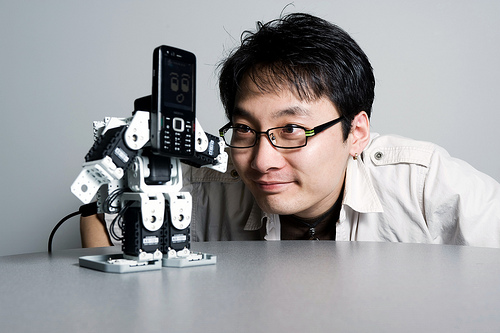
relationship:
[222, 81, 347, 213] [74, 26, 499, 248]
face of a man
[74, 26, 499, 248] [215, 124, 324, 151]
man wears glasses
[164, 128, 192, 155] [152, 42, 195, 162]
key pad on mobile phone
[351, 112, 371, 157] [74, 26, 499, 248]
ear of a man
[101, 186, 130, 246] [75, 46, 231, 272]
wires connected to robot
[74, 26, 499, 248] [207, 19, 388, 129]
man has hair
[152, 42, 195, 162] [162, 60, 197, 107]
mobile phone has a display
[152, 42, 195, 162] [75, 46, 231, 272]
mobile phone on robot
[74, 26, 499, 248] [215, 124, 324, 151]
man wearing glasses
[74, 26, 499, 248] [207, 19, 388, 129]
man has short hair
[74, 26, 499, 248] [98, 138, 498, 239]
man wearing a jacket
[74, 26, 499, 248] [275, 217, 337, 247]
man wearing a shirt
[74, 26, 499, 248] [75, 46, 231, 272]
man looking at robot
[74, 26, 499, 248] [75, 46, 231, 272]
man by a robot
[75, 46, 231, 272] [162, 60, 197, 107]
robot has display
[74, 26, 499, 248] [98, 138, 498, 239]
man has jacket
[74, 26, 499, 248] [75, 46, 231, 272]
man looking at a robot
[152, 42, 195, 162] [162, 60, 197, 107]
mobile phone has display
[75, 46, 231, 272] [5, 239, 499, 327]
robot on table